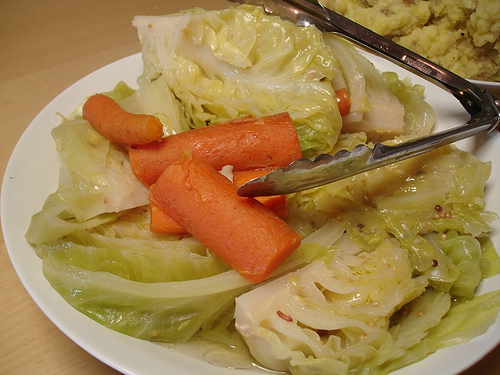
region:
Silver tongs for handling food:
[226, 0, 498, 200]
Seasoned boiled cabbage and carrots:
[26, 0, 499, 372]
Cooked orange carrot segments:
[83, 92, 303, 285]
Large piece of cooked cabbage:
[131, 3, 343, 158]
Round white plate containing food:
[0, 43, 499, 373]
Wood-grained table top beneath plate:
[0, 0, 246, 372]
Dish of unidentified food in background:
[321, 1, 498, 87]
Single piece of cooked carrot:
[146, 153, 303, 285]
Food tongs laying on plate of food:
[226, 0, 498, 197]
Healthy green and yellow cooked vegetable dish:
[27, 3, 498, 373]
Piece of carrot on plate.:
[86, 83, 156, 163]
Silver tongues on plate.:
[341, 28, 438, 160]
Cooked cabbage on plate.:
[278, 263, 370, 337]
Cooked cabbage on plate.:
[76, 220, 159, 320]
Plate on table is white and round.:
[59, 55, 399, 372]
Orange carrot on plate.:
[82, 88, 177, 149]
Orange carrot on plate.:
[142, 125, 283, 163]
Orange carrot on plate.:
[161, 164, 276, 272]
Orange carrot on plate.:
[144, 167, 317, 225]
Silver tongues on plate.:
[308, 0, 491, 239]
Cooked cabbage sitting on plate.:
[61, 136, 156, 223]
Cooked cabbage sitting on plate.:
[155, 21, 326, 130]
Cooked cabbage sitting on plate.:
[80, 239, 227, 327]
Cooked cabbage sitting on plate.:
[410, 186, 471, 240]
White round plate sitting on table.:
[11, 250, 134, 372]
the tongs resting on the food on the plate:
[226, 0, 496, 196]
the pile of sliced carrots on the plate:
[80, 91, 302, 284]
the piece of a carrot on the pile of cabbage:
[146, 142, 296, 284]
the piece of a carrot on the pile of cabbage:
[146, 165, 283, 230]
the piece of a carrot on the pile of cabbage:
[127, 110, 298, 180]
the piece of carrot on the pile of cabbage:
[81, 93, 163, 146]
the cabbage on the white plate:
[25, 3, 499, 374]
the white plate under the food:
[1, 52, 488, 374]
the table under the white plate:
[0, 1, 497, 373]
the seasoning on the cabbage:
[320, 201, 456, 347]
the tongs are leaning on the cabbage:
[221, 4, 497, 201]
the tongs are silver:
[229, 1, 497, 208]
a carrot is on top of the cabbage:
[79, 89, 171, 156]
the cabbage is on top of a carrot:
[136, 10, 358, 144]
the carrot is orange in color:
[74, 89, 166, 146]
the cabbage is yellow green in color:
[133, 8, 350, 149]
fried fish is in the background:
[327, 1, 499, 86]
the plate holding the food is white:
[2, 31, 498, 371]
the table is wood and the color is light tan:
[3, 1, 498, 369]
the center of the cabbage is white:
[230, 267, 395, 364]